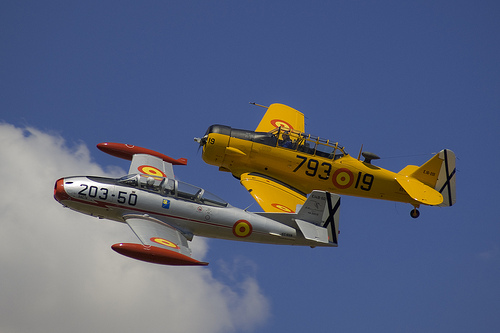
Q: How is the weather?
A: It is cloudy.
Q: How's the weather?
A: It is cloudy.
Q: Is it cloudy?
A: Yes, it is cloudy.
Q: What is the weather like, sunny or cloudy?
A: It is cloudy.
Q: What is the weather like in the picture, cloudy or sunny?
A: It is cloudy.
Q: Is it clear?
A: No, it is cloudy.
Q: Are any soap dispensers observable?
A: No, there are no soap dispensers.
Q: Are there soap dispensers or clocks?
A: No, there are no soap dispensers or clocks.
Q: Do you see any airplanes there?
A: Yes, there is an airplane.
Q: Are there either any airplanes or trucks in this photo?
A: Yes, there is an airplane.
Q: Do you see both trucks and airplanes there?
A: No, there is an airplane but no trucks.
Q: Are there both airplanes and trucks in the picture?
A: No, there is an airplane but no trucks.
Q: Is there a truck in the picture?
A: No, there are no trucks.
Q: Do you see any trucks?
A: No, there are no trucks.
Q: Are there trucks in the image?
A: No, there are no trucks.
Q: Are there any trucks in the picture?
A: No, there are no trucks.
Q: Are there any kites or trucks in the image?
A: No, there are no trucks or kites.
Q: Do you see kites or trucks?
A: No, there are no trucks or kites.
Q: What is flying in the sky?
A: The airplane is flying in the sky.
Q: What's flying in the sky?
A: The airplane is flying in the sky.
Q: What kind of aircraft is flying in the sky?
A: The aircraft is an airplane.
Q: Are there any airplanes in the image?
A: Yes, there is an airplane.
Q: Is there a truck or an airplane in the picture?
A: Yes, there is an airplane.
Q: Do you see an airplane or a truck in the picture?
A: Yes, there is an airplane.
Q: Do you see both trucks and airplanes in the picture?
A: No, there is an airplane but no trucks.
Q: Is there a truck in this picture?
A: No, there are no trucks.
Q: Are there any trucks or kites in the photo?
A: No, there are no trucks or kites.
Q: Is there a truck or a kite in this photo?
A: No, there are no trucks or kites.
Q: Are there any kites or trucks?
A: No, there are no trucks or kites.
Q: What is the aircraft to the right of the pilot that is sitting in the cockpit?
A: The aircraft is an airplane.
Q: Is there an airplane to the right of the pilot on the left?
A: Yes, there is an airplane to the right of the pilot.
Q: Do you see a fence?
A: No, there are no fences.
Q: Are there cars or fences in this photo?
A: No, there are no fences or cars.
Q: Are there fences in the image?
A: No, there are no fences.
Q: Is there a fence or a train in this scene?
A: No, there are no fences or trains.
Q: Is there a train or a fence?
A: No, there are no fences or trains.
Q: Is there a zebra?
A: No, there are no zebras.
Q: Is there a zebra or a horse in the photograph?
A: No, there are no zebras or horses.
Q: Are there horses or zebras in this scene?
A: No, there are no zebras or horses.